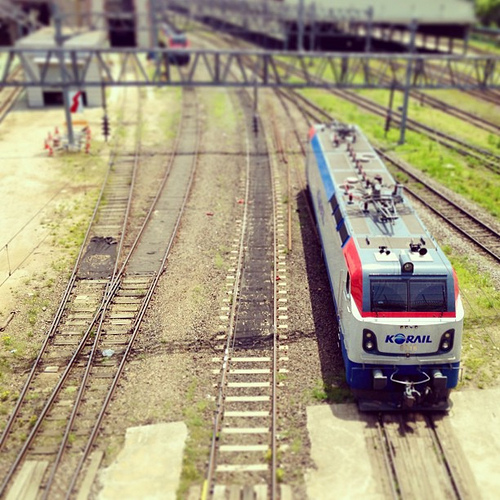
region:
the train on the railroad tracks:
[299, 115, 466, 412]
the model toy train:
[299, 120, 454, 430]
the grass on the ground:
[174, 367, 210, 487]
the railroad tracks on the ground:
[202, 320, 298, 493]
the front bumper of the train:
[370, 369, 450, 408]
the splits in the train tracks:
[30, 270, 171, 479]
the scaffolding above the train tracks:
[54, 45, 499, 95]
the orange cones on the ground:
[38, 122, 96, 158]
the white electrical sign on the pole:
[66, 89, 85, 115]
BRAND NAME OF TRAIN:
[379, 331, 438, 350]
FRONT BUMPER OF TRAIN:
[361, 396, 453, 418]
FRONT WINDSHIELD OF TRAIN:
[368, 273, 410, 311]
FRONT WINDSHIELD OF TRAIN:
[408, 276, 451, 316]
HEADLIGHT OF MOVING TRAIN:
[433, 323, 458, 356]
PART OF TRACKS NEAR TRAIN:
[242, 183, 279, 250]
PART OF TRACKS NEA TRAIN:
[216, 428, 266, 490]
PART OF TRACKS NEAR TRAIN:
[118, 288, 141, 333]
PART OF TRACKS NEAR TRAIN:
[245, 159, 272, 202]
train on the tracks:
[290, 112, 471, 427]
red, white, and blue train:
[302, 105, 467, 421]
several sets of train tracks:
[3, 48, 498, 498]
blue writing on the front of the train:
[381, 330, 437, 345]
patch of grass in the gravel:
[305, 376, 350, 403]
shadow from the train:
[293, 181, 455, 431]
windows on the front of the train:
[366, 272, 449, 320]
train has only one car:
[296, 100, 474, 461]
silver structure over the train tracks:
[1, 36, 497, 158]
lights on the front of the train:
[361, 326, 376, 353]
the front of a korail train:
[350, 256, 452, 406]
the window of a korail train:
[354, 273, 456, 310]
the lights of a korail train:
[354, 332, 379, 353]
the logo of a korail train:
[392, 313, 443, 353]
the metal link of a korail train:
[367, 373, 448, 408]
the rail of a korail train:
[374, 438, 474, 486]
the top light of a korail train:
[392, 255, 414, 279]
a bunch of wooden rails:
[148, 431, 298, 485]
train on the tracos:
[294, 102, 450, 397]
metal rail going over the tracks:
[11, 42, 487, 97]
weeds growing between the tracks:
[417, 133, 461, 180]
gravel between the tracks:
[156, 311, 208, 382]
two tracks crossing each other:
[34, 265, 156, 425]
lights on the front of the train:
[359, 331, 456, 356]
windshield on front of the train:
[371, 279, 447, 307]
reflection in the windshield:
[367, 278, 399, 308]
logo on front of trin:
[384, 328, 437, 350]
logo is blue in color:
[376, 324, 438, 350]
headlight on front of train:
[341, 336, 385, 356]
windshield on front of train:
[368, 271, 450, 320]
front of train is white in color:
[351, 320, 450, 362]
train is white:
[287, 113, 462, 433]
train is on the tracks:
[298, 104, 463, 433]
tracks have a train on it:
[232, 125, 319, 473]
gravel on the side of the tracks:
[285, 170, 341, 417]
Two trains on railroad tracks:
[152, 9, 464, 413]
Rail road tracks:
[1, 5, 493, 497]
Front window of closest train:
[370, 275, 447, 311]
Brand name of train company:
[381, 330, 433, 347]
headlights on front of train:
[365, 327, 454, 353]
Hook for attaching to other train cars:
[372, 370, 446, 410]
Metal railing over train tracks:
[3, 0, 497, 94]